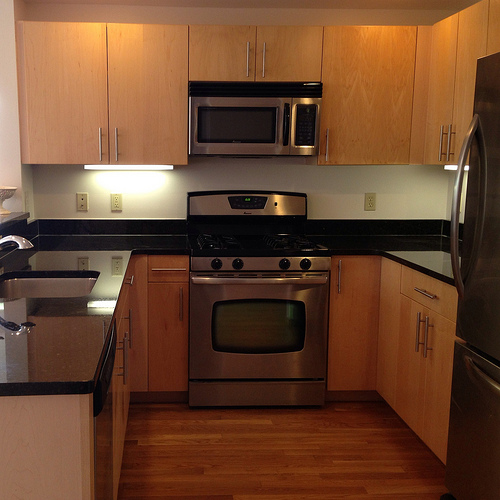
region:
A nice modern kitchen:
[0, 13, 499, 498]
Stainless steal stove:
[186, 186, 333, 413]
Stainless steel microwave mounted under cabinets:
[189, 27, 321, 160]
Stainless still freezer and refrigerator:
[445, 47, 499, 497]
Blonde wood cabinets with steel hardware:
[18, 21, 497, 492]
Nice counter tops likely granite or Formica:
[1, 212, 481, 399]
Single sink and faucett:
[1, 225, 106, 302]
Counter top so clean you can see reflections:
[0, 222, 142, 394]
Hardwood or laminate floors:
[101, 380, 488, 498]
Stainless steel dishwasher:
[6, 315, 133, 497]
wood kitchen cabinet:
[18, 15, 195, 172]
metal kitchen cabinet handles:
[80, 121, 137, 166]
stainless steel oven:
[182, 185, 334, 402]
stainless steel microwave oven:
[185, 76, 324, 171]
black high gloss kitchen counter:
[5, 215, 140, 386]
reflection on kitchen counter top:
[82, 280, 120, 321]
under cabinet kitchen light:
[72, 155, 178, 205]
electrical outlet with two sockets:
[353, 185, 384, 216]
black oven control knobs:
[203, 255, 323, 275]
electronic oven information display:
[223, 192, 279, 215]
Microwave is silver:
[180, 76, 327, 171]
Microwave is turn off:
[179, 71, 326, 164]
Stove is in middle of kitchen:
[176, 187, 338, 417]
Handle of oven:
[187, 271, 330, 293]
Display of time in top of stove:
[219, 191, 273, 213]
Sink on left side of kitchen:
[7, 231, 105, 307]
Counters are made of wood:
[11, 9, 479, 174]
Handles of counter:
[94, 123, 128, 167]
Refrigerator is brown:
[434, 39, 497, 496]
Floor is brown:
[134, 406, 436, 493]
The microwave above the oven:
[184, 90, 323, 161]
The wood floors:
[113, 391, 457, 496]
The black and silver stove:
[182, 186, 332, 414]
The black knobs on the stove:
[206, 256, 313, 276]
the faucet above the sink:
[0, 231, 36, 256]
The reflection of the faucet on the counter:
[0, 311, 34, 346]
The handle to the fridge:
[445, 111, 480, 296]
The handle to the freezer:
[461, 353, 498, 396]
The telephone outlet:
[72, 190, 91, 216]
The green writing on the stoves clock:
[243, 193, 253, 202]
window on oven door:
[209, 297, 306, 354]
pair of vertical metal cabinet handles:
[410, 308, 434, 362]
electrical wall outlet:
[103, 190, 125, 215]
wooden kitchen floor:
[136, 412, 394, 495]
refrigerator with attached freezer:
[446, 49, 498, 499]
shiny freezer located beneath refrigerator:
[445, 334, 497, 497]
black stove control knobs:
[199, 253, 319, 273]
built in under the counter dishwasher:
[65, 312, 130, 498]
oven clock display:
[239, 195, 253, 203]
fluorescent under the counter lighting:
[80, 160, 182, 172]